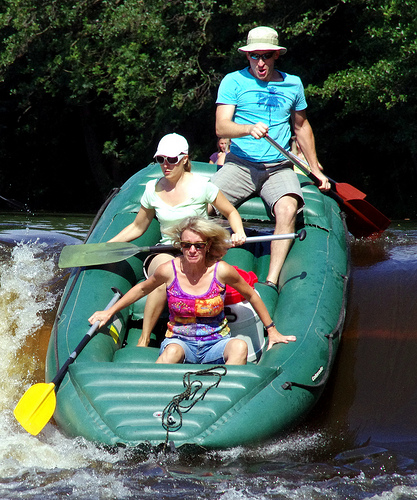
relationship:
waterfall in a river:
[347, 268, 414, 434] [21, 441, 416, 500]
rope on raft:
[162, 371, 223, 439] [52, 163, 348, 457]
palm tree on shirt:
[258, 84, 284, 131] [218, 66, 311, 171]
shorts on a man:
[212, 154, 309, 204] [212, 30, 302, 269]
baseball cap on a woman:
[153, 128, 190, 164] [128, 127, 234, 236]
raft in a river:
[52, 163, 348, 457] [21, 441, 416, 500]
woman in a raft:
[128, 127, 234, 236] [52, 163, 348, 457]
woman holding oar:
[128, 127, 234, 236] [54, 227, 311, 274]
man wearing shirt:
[212, 30, 302, 269] [218, 66, 311, 171]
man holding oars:
[212, 30, 302, 269] [252, 124, 395, 254]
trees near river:
[6, 8, 412, 160] [21, 441, 416, 500]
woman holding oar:
[115, 214, 290, 347] [8, 284, 124, 443]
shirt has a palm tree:
[218, 66, 311, 171] [258, 84, 284, 131]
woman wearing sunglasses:
[128, 127, 234, 236] [155, 154, 184, 164]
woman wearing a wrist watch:
[115, 214, 290, 347] [260, 322, 278, 332]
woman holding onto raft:
[115, 214, 290, 347] [52, 163, 348, 457]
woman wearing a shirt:
[128, 127, 234, 236] [139, 178, 223, 233]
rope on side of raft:
[334, 206, 349, 370] [52, 163, 348, 457]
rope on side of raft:
[79, 183, 114, 247] [52, 163, 348, 457]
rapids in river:
[3, 232, 68, 497] [21, 441, 416, 500]